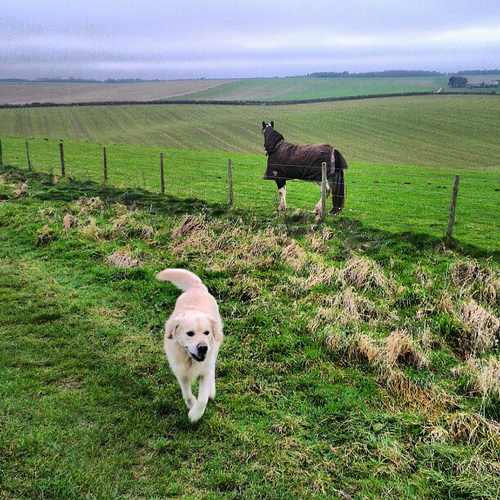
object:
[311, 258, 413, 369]
grass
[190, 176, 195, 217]
post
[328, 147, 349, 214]
tail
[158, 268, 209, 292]
tail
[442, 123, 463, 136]
tree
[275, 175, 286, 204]
legs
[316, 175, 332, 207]
legs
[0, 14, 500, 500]
pasture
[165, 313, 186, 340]
ear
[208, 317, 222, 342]
ear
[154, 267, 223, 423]
dog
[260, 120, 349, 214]
horse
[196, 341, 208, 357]
nose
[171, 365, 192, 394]
leg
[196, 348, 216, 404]
leg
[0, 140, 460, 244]
fence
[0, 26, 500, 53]
clouds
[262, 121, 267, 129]
ears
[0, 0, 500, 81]
sky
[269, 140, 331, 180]
blanket